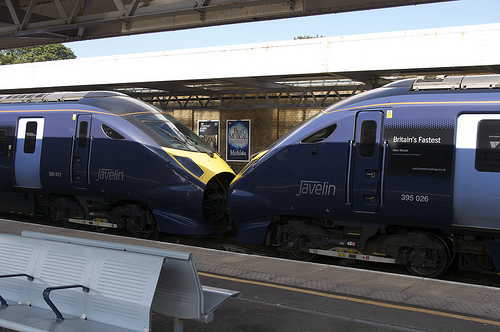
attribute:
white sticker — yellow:
[287, 173, 350, 202]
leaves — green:
[57, 46, 76, 60]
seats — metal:
[0, 227, 240, 330]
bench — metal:
[21, 228, 242, 330]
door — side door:
[347, 105, 387, 217]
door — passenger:
[12, 114, 46, 189]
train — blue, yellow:
[230, 71, 498, 286]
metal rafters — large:
[0, 0, 447, 56]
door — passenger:
[451, 110, 498, 232]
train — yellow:
[167, 139, 287, 221]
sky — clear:
[135, 6, 447, 38]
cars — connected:
[1, 72, 499, 280]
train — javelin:
[70, 53, 365, 330]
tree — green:
[0, 38, 86, 69]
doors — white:
[449, 108, 499, 231]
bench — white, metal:
[5, 227, 249, 332]